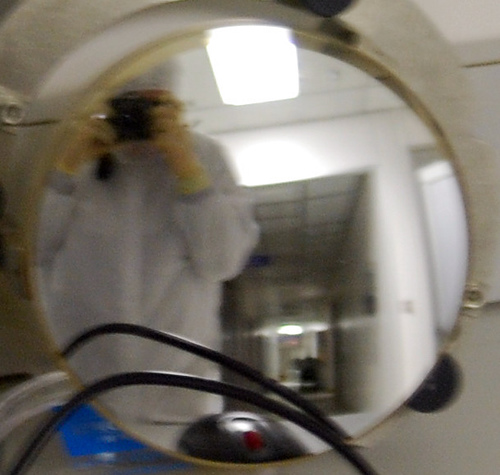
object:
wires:
[61, 323, 355, 441]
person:
[33, 58, 260, 451]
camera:
[104, 90, 161, 142]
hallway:
[223, 171, 374, 415]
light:
[278, 324, 304, 335]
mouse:
[179, 410, 308, 463]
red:
[242, 431, 265, 450]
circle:
[405, 352, 464, 413]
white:
[417, 161, 469, 339]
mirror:
[32, 27, 472, 454]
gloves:
[143, 87, 214, 191]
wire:
[0, 371, 376, 474]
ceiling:
[247, 171, 367, 284]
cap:
[126, 60, 177, 92]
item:
[54, 400, 187, 471]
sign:
[244, 254, 274, 273]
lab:
[0, 1, 499, 474]